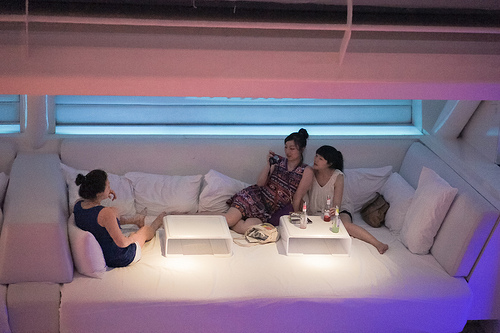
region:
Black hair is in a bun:
[71, 166, 111, 206]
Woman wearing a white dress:
[305, 144, 360, 222]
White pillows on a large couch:
[57, 152, 462, 280]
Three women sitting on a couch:
[3, 118, 497, 331]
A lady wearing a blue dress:
[69, 166, 143, 271]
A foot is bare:
[372, 236, 392, 258]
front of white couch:
[8, 136, 492, 331]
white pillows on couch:
[62, 161, 458, 278]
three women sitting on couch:
[70, 127, 387, 267]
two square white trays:
[159, 212, 350, 256]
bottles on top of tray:
[297, 196, 339, 233]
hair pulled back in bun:
[73, 168, 108, 200]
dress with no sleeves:
[225, 161, 312, 233]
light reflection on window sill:
[50, 101, 420, 133]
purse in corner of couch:
[359, 190, 389, 227]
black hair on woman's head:
[315, 143, 342, 170]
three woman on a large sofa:
[25, 100, 486, 330]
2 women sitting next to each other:
[182, 115, 431, 249]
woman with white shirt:
[295, 151, 367, 234]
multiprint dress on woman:
[218, 136, 325, 248]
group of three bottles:
[291, 198, 343, 240]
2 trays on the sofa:
[150, 190, 385, 275]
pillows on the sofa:
[76, 145, 451, 277]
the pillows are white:
[83, 123, 495, 275]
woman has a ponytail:
[277, 123, 308, 153]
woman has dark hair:
[63, 158, 125, 205]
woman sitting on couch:
[78, 168, 170, 279]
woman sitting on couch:
[242, 127, 314, 242]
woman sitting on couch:
[313, 139, 391, 255]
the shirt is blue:
[78, 200, 148, 262]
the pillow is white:
[409, 161, 449, 263]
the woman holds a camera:
[225, 110, 312, 236]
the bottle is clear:
[294, 194, 315, 231]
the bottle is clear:
[330, 199, 357, 238]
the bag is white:
[243, 211, 278, 256]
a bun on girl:
[70, 162, 86, 195]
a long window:
[26, 95, 427, 125]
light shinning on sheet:
[100, 246, 370, 292]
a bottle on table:
[285, 195, 313, 233]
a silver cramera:
[261, 151, 287, 168]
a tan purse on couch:
[355, 182, 390, 227]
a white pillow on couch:
[125, 165, 198, 206]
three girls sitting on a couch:
[57, 113, 407, 274]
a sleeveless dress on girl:
[45, 202, 128, 237]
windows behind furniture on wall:
[1, 97, 423, 137]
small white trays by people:
[158, 212, 351, 256]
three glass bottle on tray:
[299, 198, 339, 237]